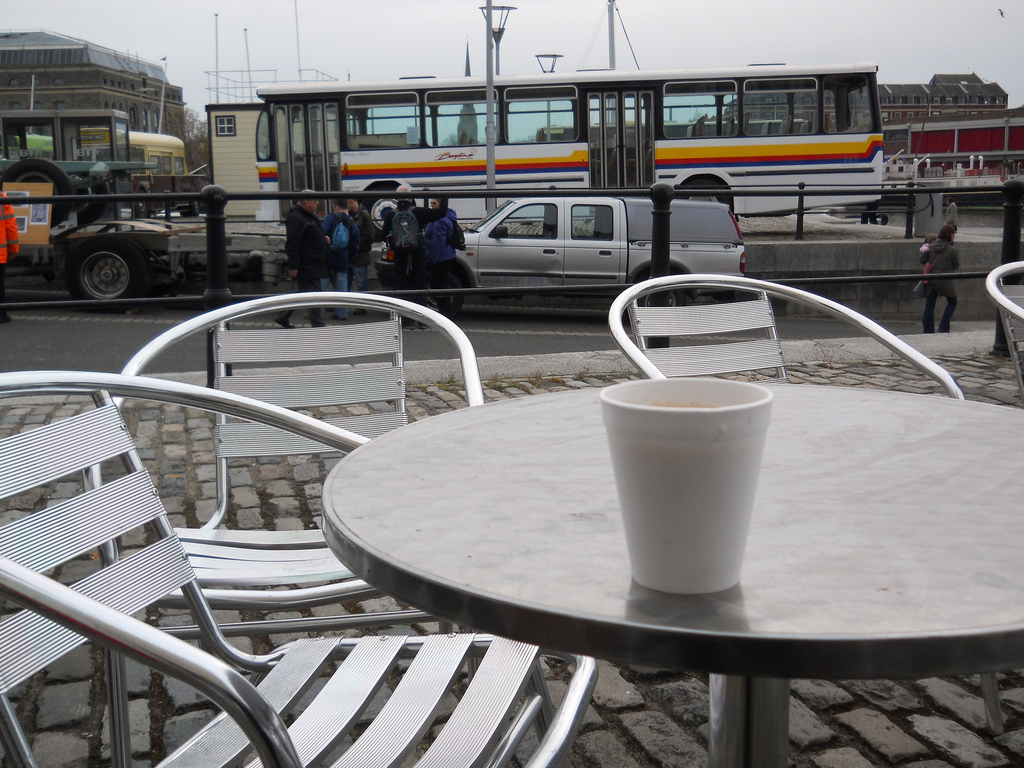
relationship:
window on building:
[345, 105, 421, 151] [846, 72, 993, 135]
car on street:
[32, 219, 195, 299] [10, 275, 991, 371]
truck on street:
[440, 201, 749, 295] [15, 242, 983, 377]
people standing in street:
[273, 173, 467, 340] [54, 260, 990, 366]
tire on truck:
[78, 255, 130, 301] [10, 199, 192, 305]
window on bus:
[345, 105, 421, 151] [244, 65, 888, 238]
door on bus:
[280, 102, 337, 217] [246, 74, 893, 254]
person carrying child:
[907, 212, 957, 334] [918, 232, 929, 297]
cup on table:
[599, 377, 772, 593] [317, 376, 989, 744]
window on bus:
[345, 105, 421, 151] [246, 74, 893, 254]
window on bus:
[352, 110, 422, 137] [266, 88, 880, 229]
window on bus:
[345, 105, 421, 151] [268, 94, 893, 211]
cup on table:
[599, 377, 772, 593] [343, 387, 1016, 744]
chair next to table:
[12, 404, 520, 765] [382, 391, 1013, 733]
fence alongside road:
[1, 179, 1019, 406] [8, 266, 1015, 392]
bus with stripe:
[249, 63, 911, 223] [251, 132, 882, 182]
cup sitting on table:
[599, 377, 772, 593] [318, 372, 1019, 662]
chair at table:
[0, 372, 602, 768] [318, 372, 1019, 662]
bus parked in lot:
[249, 63, 911, 223] [897, 175, 1010, 228]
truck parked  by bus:
[377, 198, 747, 316] [249, 63, 911, 223]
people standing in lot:
[272, 173, 465, 340] [2, 264, 986, 375]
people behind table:
[272, 173, 465, 340] [312, 366, 1024, 768]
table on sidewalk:
[312, 366, 1024, 768] [4, 329, 981, 764]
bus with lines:
[249, 63, 911, 223] [251, 134, 880, 182]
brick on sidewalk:
[833, 703, 932, 760] [593, 663, 1011, 756]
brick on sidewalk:
[833, 703, 932, 760] [566, 657, 1021, 759]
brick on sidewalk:
[32, 671, 96, 735] [20, 632, 212, 761]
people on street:
[273, 173, 467, 340] [158, 280, 619, 384]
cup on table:
[602, 359, 784, 593] [312, 366, 1024, 768]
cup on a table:
[599, 377, 772, 593] [312, 364, 974, 678]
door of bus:
[280, 107, 354, 218] [244, 65, 888, 238]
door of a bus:
[280, 102, 337, 217] [293, 63, 916, 267]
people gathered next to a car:
[273, 173, 467, 340] [374, 167, 768, 302]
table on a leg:
[312, 364, 974, 678] [700, 675, 794, 745]